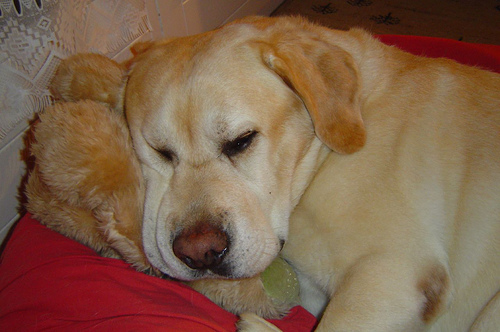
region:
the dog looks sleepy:
[105, 27, 409, 297]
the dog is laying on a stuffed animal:
[15, 38, 332, 312]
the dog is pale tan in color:
[107, 15, 487, 295]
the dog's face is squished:
[115, 46, 197, 282]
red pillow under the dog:
[4, 210, 321, 330]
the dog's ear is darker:
[254, 17, 376, 187]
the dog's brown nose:
[150, 168, 295, 300]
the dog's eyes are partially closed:
[125, 106, 306, 176]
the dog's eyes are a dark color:
[120, 105, 279, 200]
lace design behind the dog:
[11, 16, 271, 211]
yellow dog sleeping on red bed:
[36, 16, 484, 331]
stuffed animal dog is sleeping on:
[33, 60, 293, 316]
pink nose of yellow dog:
[178, 232, 225, 267]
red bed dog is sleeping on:
[22, 11, 472, 326]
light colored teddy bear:
[16, 52, 286, 312]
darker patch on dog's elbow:
[408, 264, 450, 318]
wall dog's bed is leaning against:
[5, 2, 282, 237]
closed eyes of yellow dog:
[143, 114, 268, 174]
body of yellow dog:
[333, 29, 498, 324]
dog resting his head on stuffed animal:
[24, 28, 499, 320]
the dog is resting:
[11, 5, 475, 320]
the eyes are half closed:
[130, 121, 273, 173]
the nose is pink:
[155, 214, 243, 266]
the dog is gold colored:
[72, 4, 457, 311]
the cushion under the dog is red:
[20, 12, 485, 318]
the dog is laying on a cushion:
[1, 4, 493, 314]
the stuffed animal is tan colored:
[21, 39, 146, 247]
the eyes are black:
[114, 121, 265, 171]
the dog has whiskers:
[210, 201, 300, 272]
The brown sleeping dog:
[2, 2, 499, 330]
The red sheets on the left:
[4, 208, 316, 329]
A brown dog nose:
[174, 228, 231, 273]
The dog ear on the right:
[262, 30, 366, 154]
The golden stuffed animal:
[23, 54, 304, 317]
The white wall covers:
[0, 2, 281, 236]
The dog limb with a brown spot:
[312, 158, 450, 330]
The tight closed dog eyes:
[150, 125, 260, 170]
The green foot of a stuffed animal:
[257, 259, 302, 316]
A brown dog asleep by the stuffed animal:
[24, 16, 499, 331]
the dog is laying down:
[111, 26, 474, 330]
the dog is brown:
[105, 20, 497, 323]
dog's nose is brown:
[170, 217, 237, 273]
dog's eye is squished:
[141, 136, 182, 174]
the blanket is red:
[0, 30, 498, 328]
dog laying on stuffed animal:
[7, 25, 307, 320]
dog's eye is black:
[198, 131, 258, 156]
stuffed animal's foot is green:
[256, 252, 311, 307]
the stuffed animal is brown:
[7, 41, 137, 256]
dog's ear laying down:
[266, 33, 368, 154]